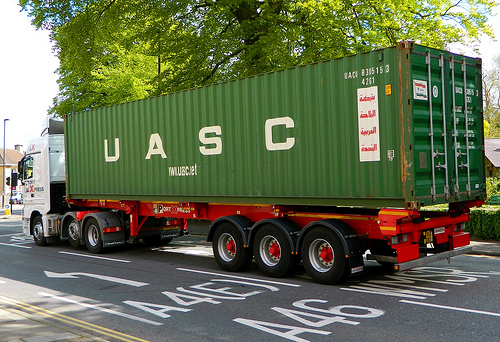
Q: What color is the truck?
A: Green.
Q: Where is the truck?
A: On the road.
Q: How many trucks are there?
A: One.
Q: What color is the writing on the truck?
A: White.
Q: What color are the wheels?
A: Black.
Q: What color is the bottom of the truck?
A: Red.